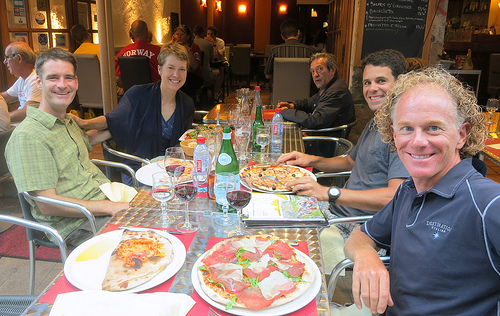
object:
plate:
[65, 226, 188, 292]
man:
[344, 65, 500, 315]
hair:
[373, 66, 490, 159]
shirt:
[359, 157, 500, 314]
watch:
[328, 185, 341, 204]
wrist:
[324, 186, 342, 202]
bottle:
[213, 125, 241, 214]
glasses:
[179, 168, 194, 236]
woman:
[64, 40, 196, 188]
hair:
[157, 41, 191, 73]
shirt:
[113, 40, 161, 86]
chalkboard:
[357, 0, 430, 69]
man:
[277, 51, 358, 158]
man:
[5, 51, 133, 247]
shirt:
[7, 103, 111, 245]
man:
[0, 41, 44, 123]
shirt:
[4, 72, 41, 115]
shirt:
[105, 81, 196, 191]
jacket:
[287, 77, 357, 157]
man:
[281, 51, 409, 258]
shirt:
[332, 111, 411, 230]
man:
[114, 19, 162, 80]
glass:
[226, 175, 253, 232]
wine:
[227, 190, 252, 207]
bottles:
[253, 103, 265, 158]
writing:
[364, 1, 428, 34]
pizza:
[238, 162, 311, 191]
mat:
[192, 235, 324, 315]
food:
[206, 236, 306, 305]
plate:
[193, 235, 322, 315]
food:
[79, 231, 174, 287]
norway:
[123, 48, 155, 60]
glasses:
[153, 172, 173, 231]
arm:
[291, 180, 411, 208]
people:
[0, 45, 134, 249]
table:
[39, 97, 339, 309]